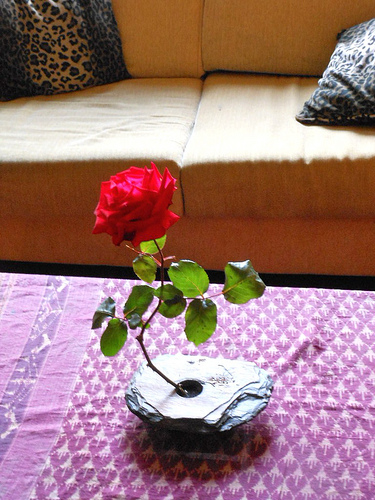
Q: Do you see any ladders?
A: No, there are no ladders.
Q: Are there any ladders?
A: No, there are no ladders.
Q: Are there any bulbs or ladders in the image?
A: No, there are no ladders or bulbs.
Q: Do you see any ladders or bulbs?
A: No, there are no ladders or bulbs.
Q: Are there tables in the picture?
A: Yes, there is a table.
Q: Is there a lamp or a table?
A: Yes, there is a table.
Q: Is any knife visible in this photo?
A: No, there are no knives.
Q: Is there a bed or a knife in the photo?
A: No, there are no knives or beds.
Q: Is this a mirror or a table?
A: This is a table.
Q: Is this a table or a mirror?
A: This is a table.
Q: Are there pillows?
A: Yes, there is a pillow.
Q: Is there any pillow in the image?
A: Yes, there is a pillow.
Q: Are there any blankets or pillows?
A: Yes, there is a pillow.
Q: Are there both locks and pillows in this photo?
A: No, there is a pillow but no locks.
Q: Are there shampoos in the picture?
A: No, there are no shampoos.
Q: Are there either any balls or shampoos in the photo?
A: No, there are no shampoos or balls.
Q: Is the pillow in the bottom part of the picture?
A: No, the pillow is in the top of the image.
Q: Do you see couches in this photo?
A: Yes, there is a couch.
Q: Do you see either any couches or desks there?
A: Yes, there is a couch.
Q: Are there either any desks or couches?
A: Yes, there is a couch.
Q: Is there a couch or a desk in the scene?
A: Yes, there is a couch.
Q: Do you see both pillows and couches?
A: Yes, there are both a couch and a pillow.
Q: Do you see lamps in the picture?
A: No, there are no lamps.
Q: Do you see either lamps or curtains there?
A: No, there are no lamps or curtains.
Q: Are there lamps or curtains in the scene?
A: No, there are no lamps or curtains.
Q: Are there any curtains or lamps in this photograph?
A: No, there are no lamps or curtains.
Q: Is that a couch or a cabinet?
A: That is a couch.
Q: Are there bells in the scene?
A: No, there are no bells.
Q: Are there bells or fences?
A: No, there are no bells or fences.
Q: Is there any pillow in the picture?
A: Yes, there is a pillow.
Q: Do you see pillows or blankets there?
A: Yes, there is a pillow.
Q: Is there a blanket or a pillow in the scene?
A: Yes, there is a pillow.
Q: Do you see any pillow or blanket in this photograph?
A: Yes, there is a pillow.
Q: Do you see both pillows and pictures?
A: No, there is a pillow but no pictures.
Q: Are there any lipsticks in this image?
A: No, there are no lipsticks.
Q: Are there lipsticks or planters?
A: No, there are no lipsticks or planters.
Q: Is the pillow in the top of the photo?
A: Yes, the pillow is in the top of the image.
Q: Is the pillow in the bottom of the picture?
A: No, the pillow is in the top of the image.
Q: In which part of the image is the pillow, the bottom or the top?
A: The pillow is in the top of the image.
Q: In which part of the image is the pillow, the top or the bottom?
A: The pillow is in the top of the image.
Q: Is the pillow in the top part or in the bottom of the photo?
A: The pillow is in the top of the image.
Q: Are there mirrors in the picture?
A: No, there are no mirrors.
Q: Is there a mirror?
A: No, there are no mirrors.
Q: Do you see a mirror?
A: No, there are no mirrors.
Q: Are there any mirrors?
A: No, there are no mirrors.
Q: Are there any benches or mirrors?
A: No, there are no mirrors or benches.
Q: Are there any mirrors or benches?
A: No, there are no mirrors or benches.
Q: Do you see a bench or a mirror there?
A: No, there are no mirrors or benches.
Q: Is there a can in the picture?
A: No, there are no cans.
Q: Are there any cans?
A: No, there are no cans.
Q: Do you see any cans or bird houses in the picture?
A: No, there are no cans or bird houses.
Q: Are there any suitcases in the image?
A: No, there are no suitcases.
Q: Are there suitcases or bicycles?
A: No, there are no suitcases or bicycles.